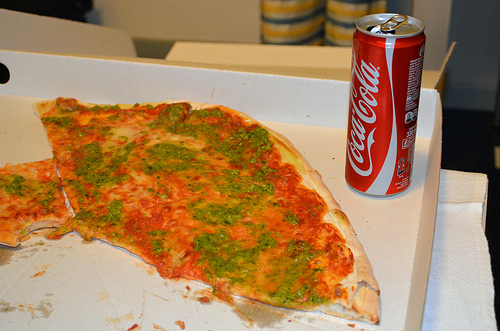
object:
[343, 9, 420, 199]
can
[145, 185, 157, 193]
herbs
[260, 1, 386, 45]
fabric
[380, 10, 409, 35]
top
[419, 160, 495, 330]
towel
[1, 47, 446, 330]
box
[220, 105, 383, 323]
crust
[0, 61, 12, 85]
hole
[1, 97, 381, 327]
pizza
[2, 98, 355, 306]
cheese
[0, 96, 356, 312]
pesto